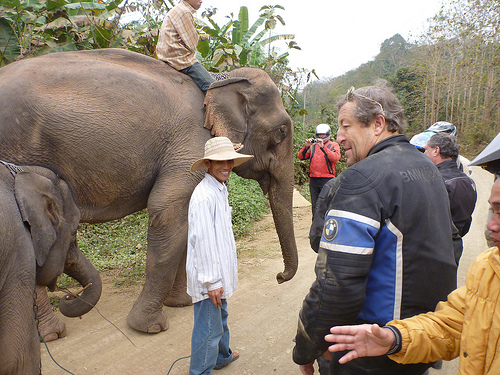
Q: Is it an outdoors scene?
A: Yes, it is outdoors.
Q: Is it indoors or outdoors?
A: It is outdoors.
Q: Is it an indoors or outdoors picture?
A: It is outdoors.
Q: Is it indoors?
A: No, it is outdoors.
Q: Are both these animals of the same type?
A: Yes, all the animals are elephants.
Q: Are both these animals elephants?
A: Yes, all the animals are elephants.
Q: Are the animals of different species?
A: No, all the animals are elephants.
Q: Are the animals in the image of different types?
A: No, all the animals are elephants.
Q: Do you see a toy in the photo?
A: No, there are no toys.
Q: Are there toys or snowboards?
A: No, there are no toys or snowboards.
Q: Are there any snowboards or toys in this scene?
A: No, there are no toys or snowboards.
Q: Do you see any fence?
A: No, there are no fences.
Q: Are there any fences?
A: No, there are no fences.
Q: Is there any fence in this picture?
A: No, there are no fences.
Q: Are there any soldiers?
A: No, there are no soldiers.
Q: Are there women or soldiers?
A: No, there are no soldiers or women.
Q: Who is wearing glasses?
A: The man is wearing glasses.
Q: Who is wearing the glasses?
A: The man is wearing glasses.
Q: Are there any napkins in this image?
A: No, there are no napkins.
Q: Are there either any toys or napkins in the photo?
A: No, there are no napkins or toys.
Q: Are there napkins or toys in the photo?
A: No, there are no napkins or toys.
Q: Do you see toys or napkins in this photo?
A: No, there are no napkins or toys.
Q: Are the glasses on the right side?
A: Yes, the glasses are on the right of the image.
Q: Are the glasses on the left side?
A: No, the glasses are on the right of the image.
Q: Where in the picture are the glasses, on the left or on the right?
A: The glasses are on the right of the image.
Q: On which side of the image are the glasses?
A: The glasses are on the right of the image.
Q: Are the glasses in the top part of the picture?
A: Yes, the glasses are in the top of the image.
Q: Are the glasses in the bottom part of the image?
A: No, the glasses are in the top of the image.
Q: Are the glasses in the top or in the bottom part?
A: The glasses are in the top of the image.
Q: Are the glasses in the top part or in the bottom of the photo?
A: The glasses are in the top of the image.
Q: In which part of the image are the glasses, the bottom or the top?
A: The glasses are in the top of the image.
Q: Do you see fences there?
A: No, there are no fences.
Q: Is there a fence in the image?
A: No, there are no fences.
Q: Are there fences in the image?
A: No, there are no fences.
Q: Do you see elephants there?
A: Yes, there is an elephant.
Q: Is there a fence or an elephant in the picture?
A: Yes, there is an elephant.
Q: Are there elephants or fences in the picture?
A: Yes, there is an elephant.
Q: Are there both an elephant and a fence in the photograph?
A: No, there is an elephant but no fences.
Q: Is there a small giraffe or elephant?
A: Yes, there is a small elephant.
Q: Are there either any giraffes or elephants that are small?
A: Yes, the elephant is small.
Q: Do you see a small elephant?
A: Yes, there is a small elephant.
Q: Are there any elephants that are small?
A: Yes, there is an elephant that is small.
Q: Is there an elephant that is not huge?
A: Yes, there is a small elephant.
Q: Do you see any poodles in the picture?
A: No, there are no poodles.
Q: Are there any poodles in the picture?
A: No, there are no poodles.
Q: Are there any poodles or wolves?
A: No, there are no poodles or wolves.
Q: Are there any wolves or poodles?
A: No, there are no poodles or wolves.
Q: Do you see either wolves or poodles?
A: No, there are no poodles or wolves.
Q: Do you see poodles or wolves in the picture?
A: No, there are no poodles or wolves.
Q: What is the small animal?
A: The animal is an elephant.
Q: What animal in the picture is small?
A: The animal is an elephant.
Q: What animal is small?
A: The animal is an elephant.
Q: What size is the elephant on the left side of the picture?
A: The elephant is small.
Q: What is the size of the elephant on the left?
A: The elephant is small.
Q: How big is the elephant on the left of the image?
A: The elephant is small.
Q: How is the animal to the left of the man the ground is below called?
A: The animal is an elephant.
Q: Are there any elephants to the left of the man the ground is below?
A: Yes, there is an elephant to the left of the man.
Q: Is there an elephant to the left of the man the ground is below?
A: Yes, there is an elephant to the left of the man.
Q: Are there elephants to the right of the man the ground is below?
A: No, the elephant is to the left of the man.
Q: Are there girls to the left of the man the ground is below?
A: No, there is an elephant to the left of the man.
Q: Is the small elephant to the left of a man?
A: Yes, the elephant is to the left of a man.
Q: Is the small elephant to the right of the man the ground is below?
A: No, the elephant is to the left of the man.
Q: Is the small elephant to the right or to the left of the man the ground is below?
A: The elephant is to the left of the man.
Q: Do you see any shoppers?
A: No, there are no shoppers.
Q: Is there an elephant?
A: Yes, there is an elephant.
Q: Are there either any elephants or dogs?
A: Yes, there is an elephant.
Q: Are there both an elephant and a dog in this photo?
A: No, there is an elephant but no dogs.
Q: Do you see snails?
A: No, there are no snails.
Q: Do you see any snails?
A: No, there are no snails.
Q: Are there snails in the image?
A: No, there are no snails.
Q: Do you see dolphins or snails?
A: No, there are no snails or dolphins.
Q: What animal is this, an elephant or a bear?
A: This is an elephant.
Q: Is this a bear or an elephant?
A: This is an elephant.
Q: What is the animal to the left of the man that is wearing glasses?
A: The animal is an elephant.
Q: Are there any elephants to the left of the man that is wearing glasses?
A: Yes, there is an elephant to the left of the man.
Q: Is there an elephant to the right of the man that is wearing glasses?
A: No, the elephant is to the left of the man.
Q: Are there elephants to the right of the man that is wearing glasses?
A: No, the elephant is to the left of the man.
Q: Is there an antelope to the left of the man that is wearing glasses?
A: No, there is an elephant to the left of the man.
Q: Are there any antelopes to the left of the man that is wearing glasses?
A: No, there is an elephant to the left of the man.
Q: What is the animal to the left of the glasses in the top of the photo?
A: The animal is an elephant.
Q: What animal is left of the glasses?
A: The animal is an elephant.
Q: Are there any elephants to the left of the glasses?
A: Yes, there is an elephant to the left of the glasses.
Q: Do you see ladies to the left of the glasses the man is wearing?
A: No, there is an elephant to the left of the glasses.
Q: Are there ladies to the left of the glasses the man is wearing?
A: No, there is an elephant to the left of the glasses.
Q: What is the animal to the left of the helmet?
A: The animal is an elephant.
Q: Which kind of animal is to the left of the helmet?
A: The animal is an elephant.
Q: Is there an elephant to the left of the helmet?
A: Yes, there is an elephant to the left of the helmet.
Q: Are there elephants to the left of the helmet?
A: Yes, there is an elephant to the left of the helmet.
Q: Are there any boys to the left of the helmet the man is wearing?
A: No, there is an elephant to the left of the helmet.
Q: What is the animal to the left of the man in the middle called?
A: The animal is an elephant.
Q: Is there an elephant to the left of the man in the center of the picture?
A: Yes, there is an elephant to the left of the man.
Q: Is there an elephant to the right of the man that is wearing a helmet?
A: No, the elephant is to the left of the man.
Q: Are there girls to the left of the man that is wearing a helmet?
A: No, there is an elephant to the left of the man.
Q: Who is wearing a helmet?
A: The man is wearing a helmet.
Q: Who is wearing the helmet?
A: The man is wearing a helmet.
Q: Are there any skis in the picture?
A: No, there are no skis.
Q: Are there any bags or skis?
A: No, there are no skis or bags.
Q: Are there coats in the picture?
A: Yes, there is a coat.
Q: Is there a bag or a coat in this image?
A: Yes, there is a coat.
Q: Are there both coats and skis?
A: No, there is a coat but no skis.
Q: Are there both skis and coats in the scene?
A: No, there is a coat but no skis.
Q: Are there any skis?
A: No, there are no skis.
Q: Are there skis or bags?
A: No, there are no skis or bags.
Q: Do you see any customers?
A: No, there are no customers.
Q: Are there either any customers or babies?
A: No, there are no customers or babies.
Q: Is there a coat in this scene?
A: Yes, there is a coat.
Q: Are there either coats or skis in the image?
A: Yes, there is a coat.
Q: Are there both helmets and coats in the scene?
A: Yes, there are both a coat and a helmet.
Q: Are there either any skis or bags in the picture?
A: No, there are no bags or skis.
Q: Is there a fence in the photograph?
A: No, there are no fences.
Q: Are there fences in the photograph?
A: No, there are no fences.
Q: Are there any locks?
A: No, there are no locks.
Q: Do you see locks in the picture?
A: No, there are no locks.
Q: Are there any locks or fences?
A: No, there are no locks or fences.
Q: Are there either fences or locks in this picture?
A: No, there are no locks or fences.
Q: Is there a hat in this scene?
A: Yes, there is a hat.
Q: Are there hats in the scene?
A: Yes, there is a hat.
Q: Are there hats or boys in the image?
A: Yes, there is a hat.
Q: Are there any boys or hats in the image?
A: Yes, there is a hat.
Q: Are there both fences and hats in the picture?
A: No, there is a hat but no fences.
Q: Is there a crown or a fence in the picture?
A: No, there are no fences or crowns.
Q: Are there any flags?
A: No, there are no flags.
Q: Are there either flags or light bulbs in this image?
A: No, there are no flags or light bulbs.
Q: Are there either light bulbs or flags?
A: No, there are no flags or light bulbs.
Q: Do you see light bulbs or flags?
A: No, there are no flags or light bulbs.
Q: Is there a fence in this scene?
A: No, there are no fences.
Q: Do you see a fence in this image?
A: No, there are no fences.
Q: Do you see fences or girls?
A: No, there are no fences or girls.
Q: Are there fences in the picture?
A: No, there are no fences.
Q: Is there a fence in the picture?
A: No, there are no fences.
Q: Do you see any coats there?
A: Yes, there is a coat.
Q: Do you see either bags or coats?
A: Yes, there is a coat.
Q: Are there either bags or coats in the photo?
A: Yes, there is a coat.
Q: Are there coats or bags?
A: Yes, there is a coat.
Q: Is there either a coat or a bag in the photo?
A: Yes, there is a coat.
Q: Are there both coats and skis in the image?
A: No, there is a coat but no skis.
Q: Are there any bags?
A: No, there are no bags.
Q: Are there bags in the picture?
A: No, there are no bags.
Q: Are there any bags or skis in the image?
A: No, there are no bags or skis.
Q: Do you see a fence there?
A: No, there are no fences.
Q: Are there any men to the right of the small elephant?
A: Yes, there is a man to the right of the elephant.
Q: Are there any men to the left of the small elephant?
A: No, the man is to the right of the elephant.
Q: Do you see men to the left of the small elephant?
A: No, the man is to the right of the elephant.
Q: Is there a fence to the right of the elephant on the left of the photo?
A: No, there is a man to the right of the elephant.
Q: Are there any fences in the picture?
A: No, there are no fences.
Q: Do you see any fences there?
A: No, there are no fences.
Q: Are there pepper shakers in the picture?
A: No, there are no pepper shakers.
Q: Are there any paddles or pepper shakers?
A: No, there are no pepper shakers or paddles.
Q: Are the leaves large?
A: Yes, the leaves are large.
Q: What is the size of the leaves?
A: The leaves are large.